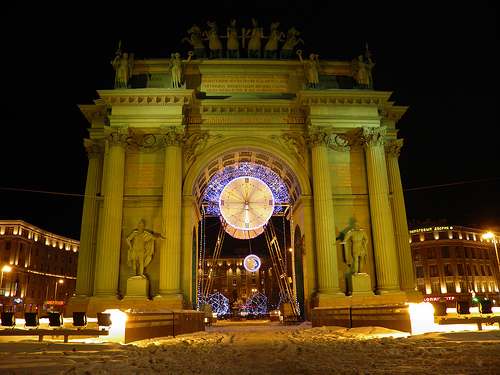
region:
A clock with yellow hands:
[219, 177, 276, 234]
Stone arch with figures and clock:
[79, 16, 431, 340]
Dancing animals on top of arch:
[173, 13, 316, 61]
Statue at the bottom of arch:
[319, 211, 394, 321]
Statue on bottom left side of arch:
[111, 211, 173, 316]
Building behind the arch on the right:
[411, 202, 494, 325]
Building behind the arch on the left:
[4, 200, 86, 330]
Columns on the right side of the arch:
[299, 97, 414, 329]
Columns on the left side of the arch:
[79, 91, 202, 331]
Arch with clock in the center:
[88, 21, 414, 329]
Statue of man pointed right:
[117, 212, 164, 306]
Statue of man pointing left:
[328, 218, 388, 301]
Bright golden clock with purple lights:
[200, 143, 298, 275]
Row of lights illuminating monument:
[0, 300, 122, 340]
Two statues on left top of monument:
[101, 31, 196, 96]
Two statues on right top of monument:
[295, 42, 390, 97]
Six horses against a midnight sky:
[175, 15, 310, 55]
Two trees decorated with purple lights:
[200, 285, 275, 315]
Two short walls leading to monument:
[102, 299, 437, 351]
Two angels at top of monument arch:
[180, 128, 309, 168]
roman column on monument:
[84, 112, 136, 311]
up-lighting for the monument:
[1, 298, 137, 339]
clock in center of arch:
[218, 175, 277, 230]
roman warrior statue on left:
[121, 215, 171, 285]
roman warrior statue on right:
[333, 215, 375, 286]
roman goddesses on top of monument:
[109, 44, 196, 91]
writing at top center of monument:
[187, 70, 292, 95]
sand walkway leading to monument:
[160, 305, 346, 365]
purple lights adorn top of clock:
[198, 157, 293, 216]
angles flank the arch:
[179, 128, 311, 166]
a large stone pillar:
[82, 134, 130, 305]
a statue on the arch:
[164, 43, 195, 94]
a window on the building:
[423, 243, 438, 265]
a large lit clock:
[197, 154, 292, 284]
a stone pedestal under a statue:
[343, 267, 377, 295]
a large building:
[0, 213, 82, 318]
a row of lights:
[0, 297, 134, 339]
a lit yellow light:
[473, 224, 498, 246]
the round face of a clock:
[217, 171, 275, 234]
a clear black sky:
[0, 0, 499, 246]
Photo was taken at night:
[8, 4, 495, 367]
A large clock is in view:
[201, 166, 285, 242]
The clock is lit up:
[195, 167, 296, 255]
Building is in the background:
[418, 212, 498, 319]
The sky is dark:
[11, 11, 73, 119]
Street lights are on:
[478, 223, 498, 255]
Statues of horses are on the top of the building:
[170, 18, 315, 63]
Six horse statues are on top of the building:
[175, 5, 335, 67]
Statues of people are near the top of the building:
[100, 45, 385, 100]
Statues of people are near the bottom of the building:
[110, 210, 376, 293]